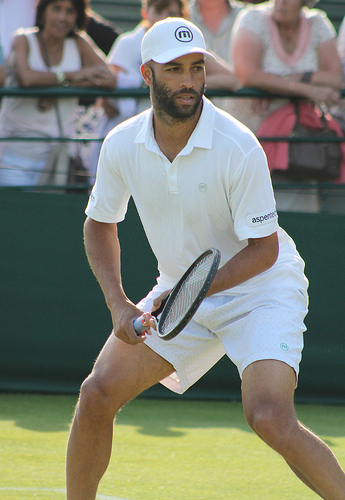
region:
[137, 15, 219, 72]
He is wearing a white hat.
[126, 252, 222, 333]
The racket is black.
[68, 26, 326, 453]
He is holding a racket.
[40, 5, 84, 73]
She is watching the tennis match.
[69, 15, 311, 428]
He is playing tennis.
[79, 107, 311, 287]
He is wearing a white shirt.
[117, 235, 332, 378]
He is wearing white shorts.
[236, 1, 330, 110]
She has a pink and white shirt on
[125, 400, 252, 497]
The ground is green.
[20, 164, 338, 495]
The sun is shining.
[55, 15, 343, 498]
Man in white shirt and white shorts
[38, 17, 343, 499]
man dressed in white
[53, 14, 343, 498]
man wearing white cap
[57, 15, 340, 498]
man dressed in white with bearded face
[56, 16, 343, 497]
man dressed in white holding a tennis raquet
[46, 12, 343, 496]
man dressed in white playing tennis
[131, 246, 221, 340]
mans tennis racquet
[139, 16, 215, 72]
mans white cap with emblem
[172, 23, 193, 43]
emblem on mans white cap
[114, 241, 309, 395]
mans white shorts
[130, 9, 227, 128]
The man is wearing a hat.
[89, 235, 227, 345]
The man is holding a tennis racket.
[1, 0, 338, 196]
Spectators are watching the tennis match.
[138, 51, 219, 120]
The man has facial hair.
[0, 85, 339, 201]
A green guardrail.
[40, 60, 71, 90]
A bracelet is on the woman's arm.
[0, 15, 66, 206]
The woman is carrying a bag.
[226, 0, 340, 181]
The woman is leaning on the guardrail.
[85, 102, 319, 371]
The man is dressed in white.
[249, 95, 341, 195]
A pink sweater is on top of the bag.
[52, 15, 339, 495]
A man playing tennis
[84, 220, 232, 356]
Tennis racket in man's hand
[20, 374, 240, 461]
Shadows on the court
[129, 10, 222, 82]
White hat on man's head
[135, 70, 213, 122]
Black facial hair on man's face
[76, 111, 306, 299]
A white shirt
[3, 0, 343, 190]
Spectators watching the game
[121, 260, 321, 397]
A pair of white shorts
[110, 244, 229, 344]
A black tennis racket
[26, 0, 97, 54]
Woman has dark hair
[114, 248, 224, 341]
a black racket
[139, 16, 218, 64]
a white and black cap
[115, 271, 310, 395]
a man's white shorts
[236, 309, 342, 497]
the leg of a man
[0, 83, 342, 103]
a long green pole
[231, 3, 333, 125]
a woman in a pink and white t-shirt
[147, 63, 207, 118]
the beard of a man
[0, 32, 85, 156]
a woman's white tank top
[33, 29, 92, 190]
a woman's shoulder bag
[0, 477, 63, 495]
a white line